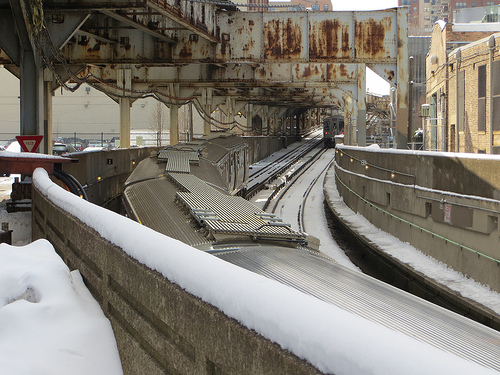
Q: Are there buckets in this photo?
A: No, there are no buckets.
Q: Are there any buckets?
A: No, there are no buckets.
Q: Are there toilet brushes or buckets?
A: No, there are no buckets or toilet brushes.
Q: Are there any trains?
A: Yes, there is a train.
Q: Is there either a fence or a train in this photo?
A: Yes, there is a train.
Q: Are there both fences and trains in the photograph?
A: No, there is a train but no fences.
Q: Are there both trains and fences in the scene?
A: No, there is a train but no fences.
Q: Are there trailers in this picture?
A: No, there are no trailers.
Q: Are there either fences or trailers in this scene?
A: No, there are no trailers or fences.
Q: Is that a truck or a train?
A: That is a train.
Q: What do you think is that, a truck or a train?
A: That is a train.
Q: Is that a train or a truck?
A: That is a train.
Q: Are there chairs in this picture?
A: No, there are no chairs.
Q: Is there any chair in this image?
A: No, there are no chairs.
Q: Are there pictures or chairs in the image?
A: No, there are no chairs or pictures.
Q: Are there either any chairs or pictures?
A: No, there are no chairs or pictures.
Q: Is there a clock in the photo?
A: No, there are no clocks.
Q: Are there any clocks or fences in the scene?
A: No, there are no clocks or fences.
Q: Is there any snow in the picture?
A: Yes, there is snow.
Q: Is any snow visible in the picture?
A: Yes, there is snow.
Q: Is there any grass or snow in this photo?
A: Yes, there is snow.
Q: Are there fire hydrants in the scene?
A: No, there are no fire hydrants.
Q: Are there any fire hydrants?
A: No, there are no fire hydrants.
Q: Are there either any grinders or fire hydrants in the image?
A: No, there are no fire hydrants or grinders.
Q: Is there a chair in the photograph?
A: No, there are no chairs.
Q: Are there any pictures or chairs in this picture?
A: No, there are no chairs or pictures.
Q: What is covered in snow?
A: The wall is covered in snow.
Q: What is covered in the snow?
A: The wall is covered in snow.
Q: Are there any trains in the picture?
A: Yes, there is a train.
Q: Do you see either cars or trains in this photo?
A: Yes, there is a train.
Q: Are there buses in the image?
A: No, there are no buses.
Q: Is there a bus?
A: No, there are no buses.